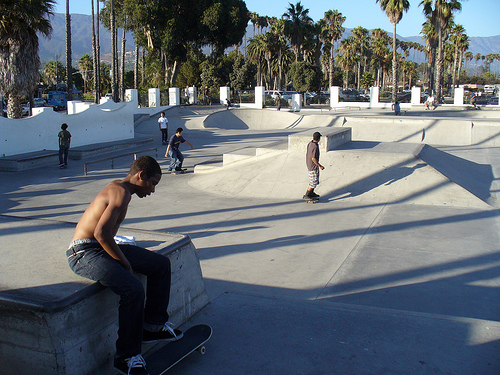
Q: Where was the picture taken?
A: It was taken at the skate park.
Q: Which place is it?
A: It is a skate park.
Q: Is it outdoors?
A: Yes, it is outdoors.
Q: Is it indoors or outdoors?
A: It is outdoors.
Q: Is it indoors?
A: No, it is outdoors.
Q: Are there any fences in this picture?
A: No, there are no fences.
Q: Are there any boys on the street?
A: Yes, there is a boy on the street.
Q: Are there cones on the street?
A: No, there is a boy on the street.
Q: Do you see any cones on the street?
A: No, there is a boy on the street.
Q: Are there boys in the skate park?
A: Yes, there is a boy in the skate park.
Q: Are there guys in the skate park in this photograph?
A: No, there is a boy in the skate park.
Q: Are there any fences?
A: No, there are no fences.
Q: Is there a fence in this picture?
A: No, there are no fences.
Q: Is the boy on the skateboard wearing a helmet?
A: No, the boy is wearing a shirt.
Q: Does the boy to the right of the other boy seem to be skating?
A: Yes, the boy is skating.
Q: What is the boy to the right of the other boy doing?
A: The boy is skating.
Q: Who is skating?
A: The boy is skating.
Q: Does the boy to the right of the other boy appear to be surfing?
A: No, the boy is skating.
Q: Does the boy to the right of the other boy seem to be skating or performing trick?
A: The boy is skating.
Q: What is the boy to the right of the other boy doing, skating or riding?
A: The boy is skating.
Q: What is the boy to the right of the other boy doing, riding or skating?
A: The boy is skating.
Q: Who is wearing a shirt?
A: The boy is wearing a shirt.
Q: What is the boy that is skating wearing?
A: The boy is wearing a shirt.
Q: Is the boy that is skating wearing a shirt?
A: Yes, the boy is wearing a shirt.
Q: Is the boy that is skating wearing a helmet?
A: No, the boy is wearing a shirt.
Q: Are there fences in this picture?
A: No, there are no fences.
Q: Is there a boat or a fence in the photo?
A: No, there are no fences or boats.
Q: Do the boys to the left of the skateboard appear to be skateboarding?
A: Yes, the boys are skateboarding.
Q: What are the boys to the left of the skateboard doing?
A: The boys are skateboarding.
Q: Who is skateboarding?
A: The boys are skateboarding.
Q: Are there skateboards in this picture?
A: Yes, there is a skateboard.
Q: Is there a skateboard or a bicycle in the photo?
A: Yes, there is a skateboard.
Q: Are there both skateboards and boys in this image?
A: Yes, there are both a skateboard and a boy.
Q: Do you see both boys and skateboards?
A: Yes, there are both a skateboard and a boy.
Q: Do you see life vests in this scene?
A: No, there are no life vests.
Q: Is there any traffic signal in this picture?
A: No, there are no traffic lights.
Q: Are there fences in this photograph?
A: No, there are no fences.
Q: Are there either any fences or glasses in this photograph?
A: No, there are no fences or glasses.